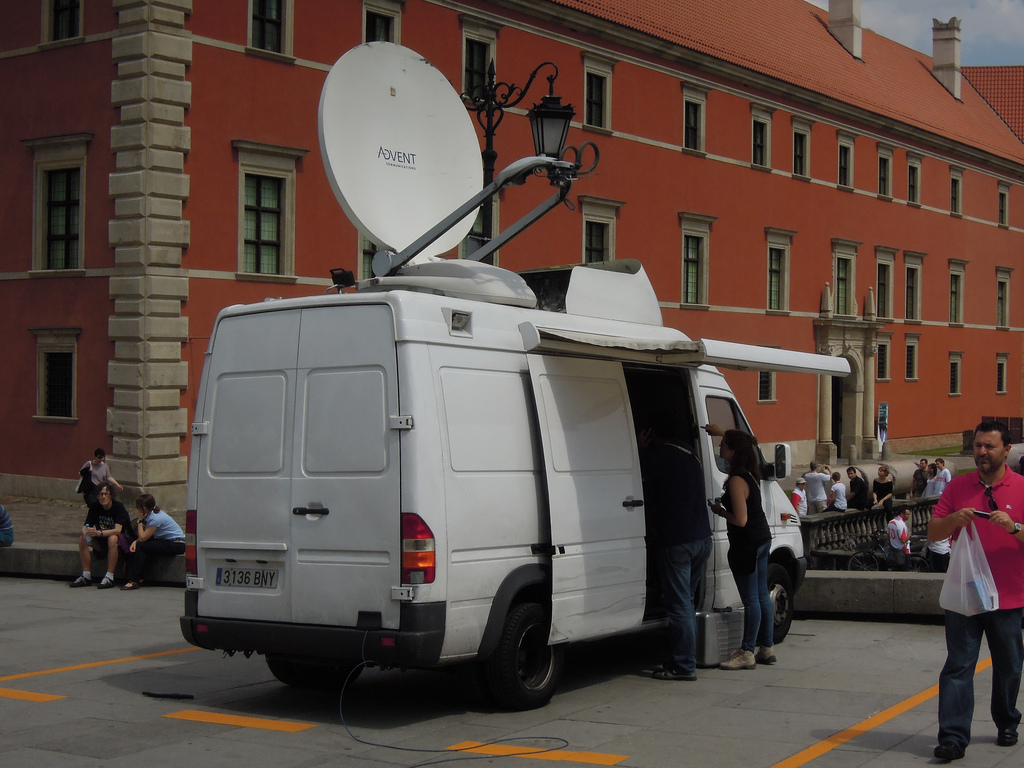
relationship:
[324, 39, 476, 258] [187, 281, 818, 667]
satellite dish on top of van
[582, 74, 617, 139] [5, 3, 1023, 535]
window in building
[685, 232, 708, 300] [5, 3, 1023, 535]
window in building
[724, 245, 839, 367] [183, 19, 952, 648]
windows on building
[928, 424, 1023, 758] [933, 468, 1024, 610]
man in pink shirt